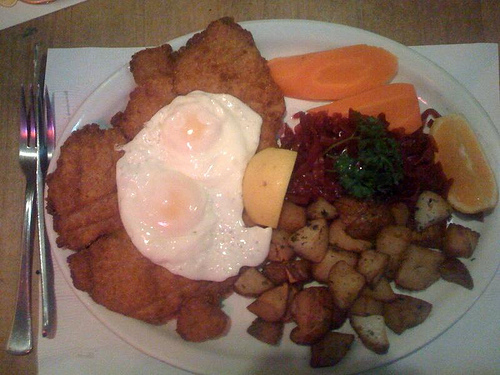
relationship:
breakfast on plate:
[29, 9, 499, 374] [44, 12, 476, 348]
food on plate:
[29, 9, 499, 374] [44, 12, 476, 348]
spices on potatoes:
[240, 191, 489, 359] [283, 200, 435, 322]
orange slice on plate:
[416, 112, 499, 216] [29, 9, 499, 374]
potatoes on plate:
[240, 191, 489, 359] [29, 9, 499, 374]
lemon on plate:
[239, 138, 308, 225] [29, 9, 499, 374]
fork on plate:
[1, 63, 87, 367] [29, 9, 499, 374]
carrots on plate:
[260, 24, 444, 148] [29, 9, 499, 374]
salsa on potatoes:
[287, 112, 447, 223] [240, 191, 489, 359]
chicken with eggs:
[41, 108, 255, 341] [102, 88, 293, 286]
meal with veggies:
[29, 9, 499, 374] [269, 35, 494, 230]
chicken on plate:
[41, 108, 255, 341] [29, 9, 499, 374]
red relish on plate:
[287, 112, 447, 223] [29, 9, 499, 374]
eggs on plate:
[102, 88, 293, 286] [29, 9, 499, 374]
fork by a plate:
[1, 63, 87, 367] [29, 9, 499, 374]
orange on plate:
[416, 112, 499, 216] [29, 9, 499, 374]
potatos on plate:
[240, 191, 489, 359] [29, 9, 499, 374]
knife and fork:
[14, 24, 74, 346] [1, 63, 87, 367]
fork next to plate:
[1, 63, 87, 367] [29, 9, 499, 374]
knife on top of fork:
[14, 24, 74, 346] [1, 63, 87, 367]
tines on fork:
[0, 75, 70, 194] [1, 63, 87, 367]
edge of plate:
[420, 289, 483, 356] [29, 9, 499, 374]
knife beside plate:
[14, 24, 74, 346] [29, 9, 499, 374]